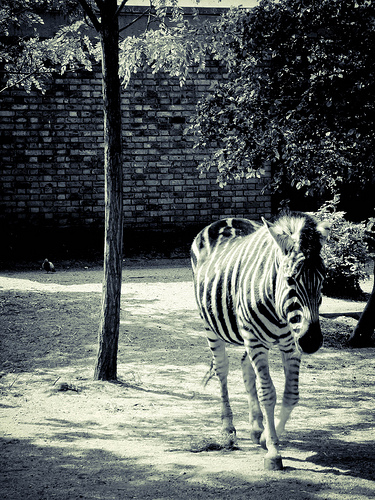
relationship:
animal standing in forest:
[189, 209, 345, 471] [241, 44, 363, 141]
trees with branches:
[233, 17, 351, 55] [86, 11, 144, 52]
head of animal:
[251, 221, 341, 346] [189, 209, 345, 471]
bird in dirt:
[18, 248, 65, 282] [18, 273, 72, 299]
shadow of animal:
[307, 430, 367, 486] [189, 209, 345, 471]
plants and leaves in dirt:
[344, 227, 374, 263] [18, 273, 72, 299]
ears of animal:
[253, 214, 339, 256] [189, 209, 345, 471]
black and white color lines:
[211, 225, 286, 282] [216, 241, 250, 279]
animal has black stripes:
[189, 209, 345, 471] [201, 256, 276, 311]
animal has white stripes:
[189, 209, 345, 471] [207, 273, 258, 302]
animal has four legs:
[189, 209, 345, 471] [179, 344, 324, 454]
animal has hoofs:
[189, 209, 345, 471] [193, 207, 359, 451]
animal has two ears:
[189, 209, 345, 471] [249, 186, 363, 281]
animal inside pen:
[189, 209, 345, 471] [48, 45, 262, 216]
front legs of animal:
[245, 346, 314, 489] [189, 209, 345, 471]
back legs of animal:
[207, 334, 256, 428] [189, 209, 345, 471]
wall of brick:
[142, 114, 164, 154] [143, 128, 214, 199]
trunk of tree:
[97, 240, 152, 342] [73, 101, 155, 213]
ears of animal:
[261, 216, 296, 256] [189, 209, 345, 471]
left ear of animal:
[314, 206, 337, 256] [189, 209, 345, 471]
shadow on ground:
[275, 430, 375, 483] [114, 396, 351, 473]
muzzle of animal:
[290, 316, 315, 358] [189, 209, 345, 471]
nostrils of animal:
[284, 325, 336, 365] [189, 209, 345, 471]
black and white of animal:
[211, 225, 286, 282] [218, 252, 339, 336]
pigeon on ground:
[18, 248, 65, 282] [114, 396, 351, 473]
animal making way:
[189, 209, 345, 471] [205, 253, 373, 376]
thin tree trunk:
[100, 149, 132, 178] [97, 240, 152, 342]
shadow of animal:
[307, 430, 367, 486] [218, 252, 339, 336]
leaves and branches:
[251, 30, 367, 104] [86, 11, 144, 52]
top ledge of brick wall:
[136, 0, 270, 25] [137, 26, 232, 157]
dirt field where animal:
[68, 349, 202, 452] [189, 209, 345, 471]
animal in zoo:
[189, 209, 345, 471] [193, 207, 359, 451]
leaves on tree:
[251, 30, 367, 104] [73, 101, 155, 213]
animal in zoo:
[189, 209, 345, 471] [3, 49, 350, 294]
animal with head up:
[189, 209, 345, 471] [286, 199, 321, 332]